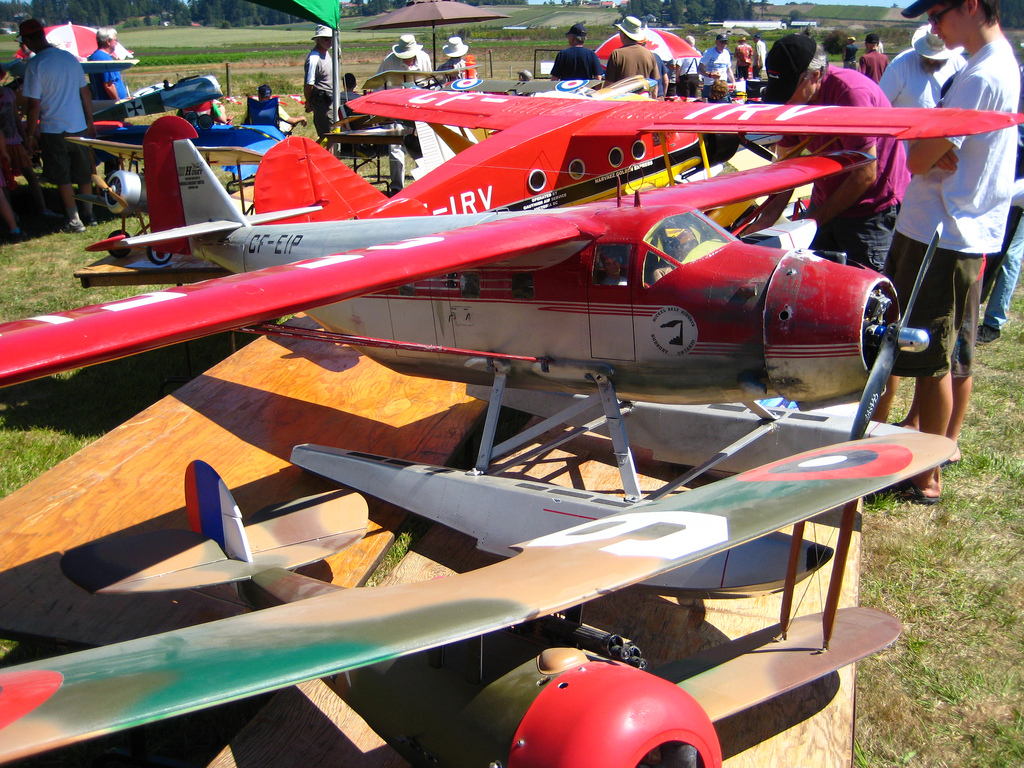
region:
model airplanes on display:
[36, 180, 777, 765]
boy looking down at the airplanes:
[887, 2, 1021, 288]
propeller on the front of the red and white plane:
[849, 211, 999, 450]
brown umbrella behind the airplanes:
[366, 0, 507, 46]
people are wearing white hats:
[378, 25, 484, 77]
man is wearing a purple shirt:
[748, 35, 898, 228]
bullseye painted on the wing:
[776, 435, 900, 490]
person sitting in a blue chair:
[239, 82, 287, 127]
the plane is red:
[221, 63, 1022, 234]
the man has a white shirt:
[866, 3, 1022, 519]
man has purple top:
[751, 25, 917, 282]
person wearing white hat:
[432, 33, 484, 104]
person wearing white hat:
[367, 21, 435, 80]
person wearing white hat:
[594, 11, 675, 94]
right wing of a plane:
[621, 47, 1018, 156]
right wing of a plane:
[328, 69, 548, 142]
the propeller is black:
[834, 213, 956, 458]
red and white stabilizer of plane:
[113, 103, 269, 231]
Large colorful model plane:
[4, 428, 960, 761]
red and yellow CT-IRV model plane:
[250, 79, 1022, 242]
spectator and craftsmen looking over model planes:
[7, 6, 1023, 509]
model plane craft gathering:
[7, 3, 1022, 766]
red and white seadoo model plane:
[1, 143, 950, 602]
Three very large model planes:
[4, 83, 1020, 763]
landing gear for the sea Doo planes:
[285, 371, 928, 600]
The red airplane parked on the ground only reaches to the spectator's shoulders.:
[253, 86, 1021, 224]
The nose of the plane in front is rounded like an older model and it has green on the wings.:
[3, 436, 959, 763]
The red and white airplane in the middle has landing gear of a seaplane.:
[2, 146, 942, 599]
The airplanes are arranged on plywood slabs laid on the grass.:
[15, 331, 870, 766]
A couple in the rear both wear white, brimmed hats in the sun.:
[378, 35, 480, 86]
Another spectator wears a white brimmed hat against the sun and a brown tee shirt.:
[606, 12, 663, 80]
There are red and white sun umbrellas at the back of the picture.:
[15, 21, 132, 63]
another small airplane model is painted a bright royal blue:
[70, 120, 282, 263]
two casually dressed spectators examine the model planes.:
[759, 7, 1015, 497]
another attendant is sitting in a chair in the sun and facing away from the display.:
[245, 85, 306, 133]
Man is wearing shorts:
[867, 216, 986, 391]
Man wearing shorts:
[880, 223, 1002, 382]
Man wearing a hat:
[750, 21, 826, 113]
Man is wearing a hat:
[756, 24, 826, 111]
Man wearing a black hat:
[744, 17, 830, 110]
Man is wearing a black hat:
[741, 24, 825, 107]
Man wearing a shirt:
[887, 39, 1021, 262]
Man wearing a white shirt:
[886, 33, 1020, 262]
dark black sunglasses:
[918, 4, 950, 27]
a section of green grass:
[854, 332, 1022, 765]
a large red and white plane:
[95, 72, 1020, 392]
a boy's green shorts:
[883, 218, 1002, 393]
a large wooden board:
[2, 318, 477, 666]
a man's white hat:
[608, 16, 647, 45]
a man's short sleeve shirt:
[23, 47, 91, 134]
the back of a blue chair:
[247, 94, 276, 127]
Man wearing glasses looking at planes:
[884, 0, 1020, 515]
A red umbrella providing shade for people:
[348, 0, 517, 89]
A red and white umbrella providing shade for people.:
[18, 7, 145, 66]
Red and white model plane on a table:
[0, 119, 955, 592]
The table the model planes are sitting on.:
[2, 247, 906, 764]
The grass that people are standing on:
[853, 250, 1019, 757]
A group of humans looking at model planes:
[2, 10, 1021, 511]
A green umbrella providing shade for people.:
[264, 0, 350, 73]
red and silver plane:
[23, 108, 929, 473]